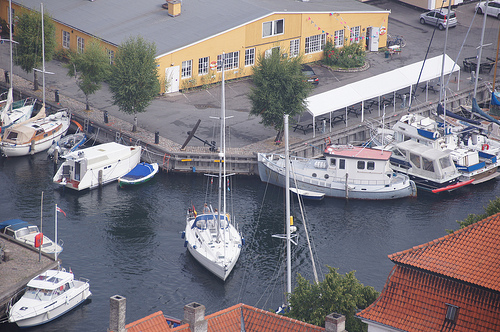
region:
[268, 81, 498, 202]
Boats anchored at a pier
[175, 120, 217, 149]
A very large anchor as decoration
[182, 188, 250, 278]
A white boat coming in from the sea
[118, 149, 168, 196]
A small boat or a jet ski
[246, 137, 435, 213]
A large fishing boat anchored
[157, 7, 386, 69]
A large yellow building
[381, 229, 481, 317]
Red roof on a building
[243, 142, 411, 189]
A large fishing boat parked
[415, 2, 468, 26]
A white SUV parked near the pier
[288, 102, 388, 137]
Picnic tables under an awning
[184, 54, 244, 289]
a white boat in water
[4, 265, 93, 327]
a docked white boat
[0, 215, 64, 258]
a docked white boat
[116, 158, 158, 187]
a docked white boat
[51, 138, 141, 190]
a docked white boat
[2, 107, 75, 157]
a docked white boat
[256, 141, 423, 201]
a docked white boat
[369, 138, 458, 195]
a docked white boat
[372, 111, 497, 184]
a docked white boat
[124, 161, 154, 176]
a blue boat tarp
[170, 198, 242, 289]
boat at the marina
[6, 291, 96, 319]
boat at the marina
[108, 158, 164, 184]
boat at the marina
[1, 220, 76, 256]
boat at the marina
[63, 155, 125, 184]
boat at the marina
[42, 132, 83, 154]
boat at the marina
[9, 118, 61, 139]
boat at the marina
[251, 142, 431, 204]
boat at the marina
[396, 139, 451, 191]
boat at the marina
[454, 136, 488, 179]
boat at the marina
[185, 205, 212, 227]
person standing on boat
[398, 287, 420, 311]
red tiles on roof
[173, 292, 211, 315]
gray chimney on top of roof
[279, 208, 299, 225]
yellow object on ships's mast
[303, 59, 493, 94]
large white cover on tent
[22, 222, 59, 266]
red sign on silver post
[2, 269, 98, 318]
white boat in water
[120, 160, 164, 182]
blue cover on the boat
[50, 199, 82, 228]
flag flying on the silver mast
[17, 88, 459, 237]
boats parked in the marina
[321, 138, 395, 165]
Red roof of boat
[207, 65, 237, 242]
White mast of boat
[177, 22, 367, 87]
Windows on tan building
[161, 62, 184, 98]
White door on building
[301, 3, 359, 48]
Colored flags on building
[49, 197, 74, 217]
Red and white flag on pole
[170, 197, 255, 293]
White boat on water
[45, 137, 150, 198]
White boat docked at pier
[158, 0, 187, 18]
Tan chimney on building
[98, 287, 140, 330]
Gray chimney on building